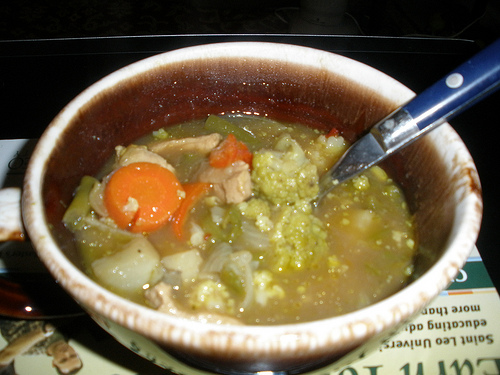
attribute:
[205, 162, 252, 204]
meat — stew meat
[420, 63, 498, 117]
dot — white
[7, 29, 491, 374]
bowl — brown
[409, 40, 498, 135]
handle — blue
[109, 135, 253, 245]
carrot — sliced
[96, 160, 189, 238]
carrot — round, sliced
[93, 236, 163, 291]
potato — small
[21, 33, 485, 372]
soup bowl — round, brown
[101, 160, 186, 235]
orange carrot — sliced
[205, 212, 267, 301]
onions — sliced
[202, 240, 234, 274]
onion — white, cooked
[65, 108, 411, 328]
soup — vegetable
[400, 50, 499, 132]
handle — blue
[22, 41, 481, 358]
rim — white